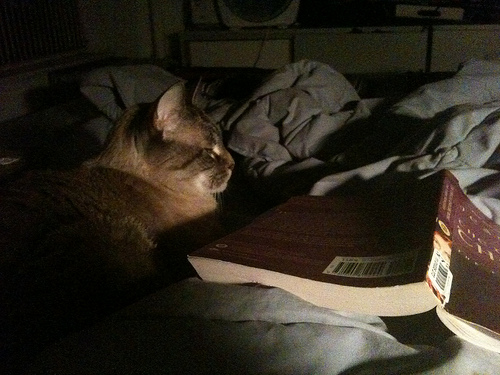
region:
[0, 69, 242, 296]
cat sleeping on a comforter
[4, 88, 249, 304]
cat sleeping in semi-darkness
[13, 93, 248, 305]
a tabby cat laying down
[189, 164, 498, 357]
an open book on the bed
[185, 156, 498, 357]
an open softback book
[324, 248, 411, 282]
bar code on the book cover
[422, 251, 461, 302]
a second bar code on the book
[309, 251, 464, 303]
pair of bar codes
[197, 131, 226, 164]
closed eye of the cat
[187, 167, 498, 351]
book with a brown cover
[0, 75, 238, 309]
cat asleep on bed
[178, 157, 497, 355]
book on a bed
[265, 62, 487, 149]
comforter on a bed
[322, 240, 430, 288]
upc code on a book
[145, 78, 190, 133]
right ear of a cat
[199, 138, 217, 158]
closed right eye of a cat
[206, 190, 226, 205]
whiskers on a cat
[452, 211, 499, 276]
title of a book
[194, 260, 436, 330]
pages of a book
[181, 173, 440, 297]
back cover of a book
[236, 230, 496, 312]
The book is open.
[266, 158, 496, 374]
The book is on the bed.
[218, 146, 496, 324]
The book is laying down.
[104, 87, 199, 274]
The cat is brown.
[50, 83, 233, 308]
The cat is laying on the bed.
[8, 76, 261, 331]
The cat is sleeping.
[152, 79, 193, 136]
Her ear is brown.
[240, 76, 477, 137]
The blanket is grey.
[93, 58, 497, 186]
The blanket is wrinkled up.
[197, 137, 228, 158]
Her eye is white.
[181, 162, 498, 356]
books is turned over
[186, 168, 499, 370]
book on the top cover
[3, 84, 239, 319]
cat is lying down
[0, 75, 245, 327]
cat lying on cover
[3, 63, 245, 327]
cat next to book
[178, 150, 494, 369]
book next to cat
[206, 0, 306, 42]
fan on top of shelf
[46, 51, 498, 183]
cover is bunched on bed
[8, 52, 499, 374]
cover is a green/gray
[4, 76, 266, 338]
cat is asleep on bed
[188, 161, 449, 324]
Back of book on bed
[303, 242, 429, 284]
White label on book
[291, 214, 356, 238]
White lettering on book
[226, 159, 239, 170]
Cats nose is brown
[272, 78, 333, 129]
Grey blanket on bed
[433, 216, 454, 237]
Yellow sticker on book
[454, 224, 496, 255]
Yellow lettering on book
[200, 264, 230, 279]
White paper in book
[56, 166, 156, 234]
Yellowish brown stripes on cat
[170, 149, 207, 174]
Dark brown stripe on cats face